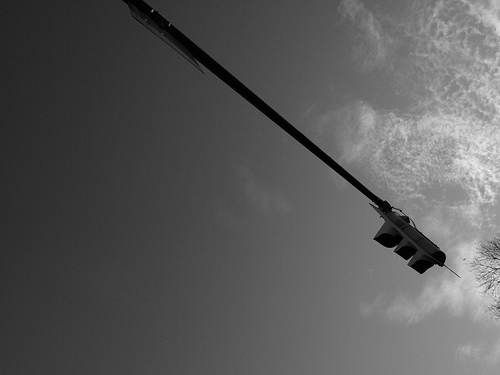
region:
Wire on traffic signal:
[389, 199, 417, 228]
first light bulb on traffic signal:
[374, 217, 398, 248]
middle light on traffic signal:
[391, 237, 417, 262]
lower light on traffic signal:
[413, 249, 436, 287]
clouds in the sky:
[356, 93, 498, 219]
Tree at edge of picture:
[458, 215, 496, 332]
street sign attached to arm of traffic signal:
[126, 9, 228, 81]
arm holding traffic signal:
[164, 6, 393, 215]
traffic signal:
[370, 193, 466, 296]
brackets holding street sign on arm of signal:
[145, 4, 186, 32]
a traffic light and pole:
[133, 0, 444, 270]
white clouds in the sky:
[330, 0, 496, 320]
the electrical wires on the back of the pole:
[385, 195, 415, 226]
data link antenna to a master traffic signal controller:
[440, 260, 460, 280]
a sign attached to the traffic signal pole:
[128, 3, 206, 75]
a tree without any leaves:
[466, 227, 496, 312]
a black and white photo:
[0, 0, 495, 372]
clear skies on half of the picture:
[0, 0, 242, 370]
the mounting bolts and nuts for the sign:
[146, 5, 151, 10]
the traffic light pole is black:
[125, 0, 392, 207]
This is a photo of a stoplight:
[63, 16, 485, 309]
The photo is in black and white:
[67, 0, 463, 332]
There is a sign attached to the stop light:
[111, 3, 479, 341]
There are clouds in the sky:
[116, 11, 497, 339]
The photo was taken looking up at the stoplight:
[77, 9, 489, 319]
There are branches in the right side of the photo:
[397, 172, 497, 343]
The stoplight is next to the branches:
[131, 5, 497, 311]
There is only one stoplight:
[108, 8, 481, 350]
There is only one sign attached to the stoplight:
[90, 10, 475, 316]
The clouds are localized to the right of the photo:
[10, 10, 496, 335]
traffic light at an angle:
[157, 52, 457, 283]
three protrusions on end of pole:
[356, 185, 468, 305]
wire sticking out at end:
[440, 260, 465, 285]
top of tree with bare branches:
[461, 225, 493, 320]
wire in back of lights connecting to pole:
[360, 185, 421, 236]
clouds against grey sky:
[406, 47, 481, 202]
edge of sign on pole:
[131, 7, 208, 87]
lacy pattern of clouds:
[420, 15, 486, 120]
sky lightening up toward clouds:
[45, 270, 470, 355]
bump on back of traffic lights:
[390, 205, 415, 231]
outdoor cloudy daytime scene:
[9, 6, 496, 363]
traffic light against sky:
[120, 5, 480, 288]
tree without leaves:
[469, 243, 499, 328]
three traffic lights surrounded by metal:
[358, 207, 461, 279]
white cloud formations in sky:
[291, 0, 498, 365]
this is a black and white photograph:
[3, 1, 492, 366]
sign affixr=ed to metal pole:
[131, 3, 213, 78]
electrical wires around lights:
[367, 187, 463, 289]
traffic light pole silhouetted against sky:
[108, 1, 493, 283]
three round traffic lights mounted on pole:
[105, 7, 450, 284]